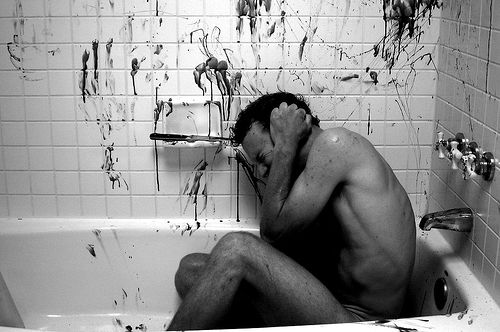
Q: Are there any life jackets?
A: No, there are no life jackets.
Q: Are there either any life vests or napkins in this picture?
A: No, there are no life vests or napkins.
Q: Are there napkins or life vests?
A: No, there are no life vests or napkins.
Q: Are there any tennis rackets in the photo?
A: No, there are no tennis rackets.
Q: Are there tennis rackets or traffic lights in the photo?
A: No, there are no tennis rackets or traffic lights.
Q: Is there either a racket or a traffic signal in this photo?
A: No, there are no rackets or traffic lights.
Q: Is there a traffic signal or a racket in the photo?
A: No, there are no rackets or traffic lights.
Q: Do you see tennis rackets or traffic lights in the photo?
A: No, there are no tennis rackets or traffic lights.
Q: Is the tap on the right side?
A: Yes, the tap is on the right of the image.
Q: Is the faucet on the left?
A: No, the faucet is on the right of the image.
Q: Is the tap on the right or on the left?
A: The tap is on the right of the image.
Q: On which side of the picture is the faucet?
A: The faucet is on the right of the image.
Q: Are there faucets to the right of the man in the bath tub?
A: Yes, there is a faucet to the right of the man.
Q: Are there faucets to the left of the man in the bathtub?
A: No, the faucet is to the right of the man.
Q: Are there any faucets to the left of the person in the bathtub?
A: No, the faucet is to the right of the man.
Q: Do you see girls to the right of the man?
A: No, there is a faucet to the right of the man.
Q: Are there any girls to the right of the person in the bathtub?
A: No, there is a faucet to the right of the man.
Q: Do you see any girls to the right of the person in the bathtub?
A: No, there is a faucet to the right of the man.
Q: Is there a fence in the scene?
A: No, there are no fences.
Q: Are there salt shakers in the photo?
A: No, there are no salt shakers.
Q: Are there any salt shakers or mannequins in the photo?
A: No, there are no salt shakers or mannequins.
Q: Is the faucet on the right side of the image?
A: Yes, the faucet is on the right of the image.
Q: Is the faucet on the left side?
A: No, the faucet is on the right of the image.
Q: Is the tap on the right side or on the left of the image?
A: The tap is on the right of the image.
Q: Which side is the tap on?
A: The tap is on the right of the image.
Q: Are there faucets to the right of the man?
A: Yes, there is a faucet to the right of the man.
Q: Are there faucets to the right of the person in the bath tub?
A: Yes, there is a faucet to the right of the man.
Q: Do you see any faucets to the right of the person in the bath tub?
A: Yes, there is a faucet to the right of the man.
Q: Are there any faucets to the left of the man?
A: No, the faucet is to the right of the man.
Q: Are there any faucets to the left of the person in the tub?
A: No, the faucet is to the right of the man.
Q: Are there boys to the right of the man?
A: No, there is a faucet to the right of the man.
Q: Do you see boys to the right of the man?
A: No, there is a faucet to the right of the man.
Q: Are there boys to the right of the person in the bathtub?
A: No, there is a faucet to the right of the man.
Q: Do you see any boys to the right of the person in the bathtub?
A: No, there is a faucet to the right of the man.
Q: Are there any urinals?
A: No, there are no urinals.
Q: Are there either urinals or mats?
A: No, there are no urinals or mats.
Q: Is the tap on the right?
A: Yes, the tap is on the right of the image.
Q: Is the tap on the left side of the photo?
A: No, the tap is on the right of the image.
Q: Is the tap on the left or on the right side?
A: The tap is on the right of the image.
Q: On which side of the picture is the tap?
A: The tap is on the right of the image.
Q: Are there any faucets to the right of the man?
A: Yes, there is a faucet to the right of the man.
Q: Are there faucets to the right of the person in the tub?
A: Yes, there is a faucet to the right of the man.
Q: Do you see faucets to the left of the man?
A: No, the faucet is to the right of the man.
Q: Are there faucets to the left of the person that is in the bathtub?
A: No, the faucet is to the right of the man.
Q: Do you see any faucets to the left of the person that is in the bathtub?
A: No, the faucet is to the right of the man.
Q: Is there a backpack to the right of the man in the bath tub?
A: No, there is a faucet to the right of the man.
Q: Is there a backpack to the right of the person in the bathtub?
A: No, there is a faucet to the right of the man.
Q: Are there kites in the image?
A: No, there are no kites.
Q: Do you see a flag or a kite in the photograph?
A: No, there are no kites or flags.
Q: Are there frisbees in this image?
A: No, there are no frisbees.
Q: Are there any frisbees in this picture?
A: No, there are no frisbees.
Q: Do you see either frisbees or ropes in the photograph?
A: No, there are no frisbees or ropes.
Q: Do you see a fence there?
A: No, there are no fences.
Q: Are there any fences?
A: No, there are no fences.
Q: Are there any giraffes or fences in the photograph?
A: No, there are no fences or giraffes.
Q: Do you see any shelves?
A: No, there are no shelves.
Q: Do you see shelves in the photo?
A: No, there are no shelves.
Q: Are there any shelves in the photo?
A: No, there are no shelves.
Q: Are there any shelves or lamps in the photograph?
A: No, there are no shelves or lamps.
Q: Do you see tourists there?
A: No, there are no tourists.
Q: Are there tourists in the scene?
A: No, there are no tourists.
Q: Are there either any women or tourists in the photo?
A: No, there are no tourists or women.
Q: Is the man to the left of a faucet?
A: Yes, the man is to the left of a faucet.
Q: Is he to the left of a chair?
A: No, the man is to the left of a faucet.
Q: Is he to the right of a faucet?
A: No, the man is to the left of a faucet.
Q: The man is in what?
A: The man is in the bathtub.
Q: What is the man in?
A: The man is in the bathtub.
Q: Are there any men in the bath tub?
A: Yes, there is a man in the bath tub.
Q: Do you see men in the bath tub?
A: Yes, there is a man in the bath tub.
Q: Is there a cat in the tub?
A: No, there is a man in the tub.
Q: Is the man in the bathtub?
A: Yes, the man is in the bathtub.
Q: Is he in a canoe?
A: No, the man is in the bathtub.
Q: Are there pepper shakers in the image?
A: No, there are no pepper shakers.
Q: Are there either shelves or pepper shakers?
A: No, there are no pepper shakers or shelves.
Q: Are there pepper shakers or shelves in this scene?
A: No, there are no pepper shakers or shelves.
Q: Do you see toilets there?
A: No, there are no toilets.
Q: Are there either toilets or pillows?
A: No, there are no toilets or pillows.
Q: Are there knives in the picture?
A: Yes, there is a knife.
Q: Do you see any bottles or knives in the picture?
A: Yes, there is a knife.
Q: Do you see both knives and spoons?
A: No, there is a knife but no spoons.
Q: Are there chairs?
A: No, there are no chairs.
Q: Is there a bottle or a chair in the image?
A: No, there are no chairs or bottles.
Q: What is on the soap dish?
A: The knife is on the soap dish.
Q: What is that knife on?
A: The knife is on the soap dish.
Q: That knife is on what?
A: The knife is on the soap dish.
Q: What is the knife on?
A: The knife is on the soap dish.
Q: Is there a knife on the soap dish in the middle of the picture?
A: Yes, there is a knife on the soap dish.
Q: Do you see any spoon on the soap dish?
A: No, there is a knife on the soap dish.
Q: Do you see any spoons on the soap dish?
A: No, there is a knife on the soap dish.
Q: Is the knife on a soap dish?
A: Yes, the knife is on a soap dish.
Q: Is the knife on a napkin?
A: No, the knife is on a soap dish.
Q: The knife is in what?
A: The knife is in the bathtub.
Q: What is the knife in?
A: The knife is in the bathtub.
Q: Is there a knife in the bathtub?
A: Yes, there is a knife in the bathtub.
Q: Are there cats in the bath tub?
A: No, there is a knife in the bath tub.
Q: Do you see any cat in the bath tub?
A: No, there is a knife in the bath tub.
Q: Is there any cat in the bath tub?
A: No, there is a knife in the bath tub.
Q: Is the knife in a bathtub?
A: Yes, the knife is in a bathtub.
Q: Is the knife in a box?
A: No, the knife is in a bathtub.